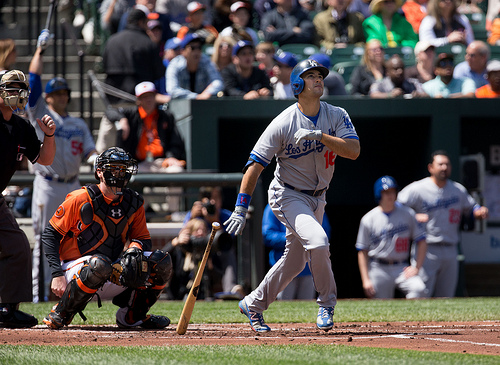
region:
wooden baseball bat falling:
[172, 215, 228, 340]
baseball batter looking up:
[216, 40, 368, 346]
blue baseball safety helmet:
[279, 52, 332, 102]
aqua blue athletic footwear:
[234, 290, 274, 346]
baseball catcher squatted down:
[39, 138, 181, 338]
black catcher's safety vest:
[68, 174, 153, 276]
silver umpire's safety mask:
[3, 65, 32, 123]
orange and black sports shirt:
[42, 184, 159, 294]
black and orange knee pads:
[72, 243, 181, 295]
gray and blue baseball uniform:
[232, 97, 366, 338]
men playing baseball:
[22, 23, 375, 341]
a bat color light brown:
[170, 212, 227, 342]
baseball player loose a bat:
[166, 45, 366, 337]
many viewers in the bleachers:
[158, 0, 493, 82]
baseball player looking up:
[261, 45, 371, 164]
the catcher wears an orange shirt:
[31, 133, 186, 340]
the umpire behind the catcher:
[5, 66, 60, 331]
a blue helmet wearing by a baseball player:
[273, 49, 348, 126]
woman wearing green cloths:
[358, 0, 428, 58]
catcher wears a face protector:
[86, 138, 146, 199]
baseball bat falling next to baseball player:
[171, 215, 222, 340]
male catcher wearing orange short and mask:
[40, 148, 171, 328]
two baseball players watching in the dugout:
[358, 152, 479, 299]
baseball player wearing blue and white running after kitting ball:
[230, 56, 361, 334]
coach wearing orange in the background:
[111, 76, 187, 171]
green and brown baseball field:
[1, 300, 498, 363]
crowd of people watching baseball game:
[104, 3, 497, 100]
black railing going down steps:
[56, 18, 88, 108]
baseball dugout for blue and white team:
[191, 99, 499, 300]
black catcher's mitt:
[119, 248, 148, 285]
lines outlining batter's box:
[79, 308, 451, 346]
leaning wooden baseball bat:
[172, 218, 220, 338]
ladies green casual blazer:
[359, 8, 421, 60]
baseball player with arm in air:
[23, 3, 105, 313]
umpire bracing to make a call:
[0, 61, 65, 342]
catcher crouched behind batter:
[36, 138, 195, 350]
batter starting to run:
[215, 53, 382, 340]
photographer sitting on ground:
[159, 210, 241, 303]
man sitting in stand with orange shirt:
[105, 77, 195, 167]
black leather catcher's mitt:
[115, 243, 153, 300]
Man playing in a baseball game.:
[245, 50, 363, 337]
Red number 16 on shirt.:
[312, 140, 338, 178]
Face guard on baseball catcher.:
[92, 147, 139, 195]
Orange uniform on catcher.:
[49, 143, 171, 330]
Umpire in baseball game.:
[0, 61, 57, 340]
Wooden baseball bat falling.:
[183, 214, 222, 335]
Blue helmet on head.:
[370, 168, 401, 207]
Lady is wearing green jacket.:
[362, 0, 420, 52]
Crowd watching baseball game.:
[192, 3, 461, 97]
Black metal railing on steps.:
[49, 8, 116, 110]